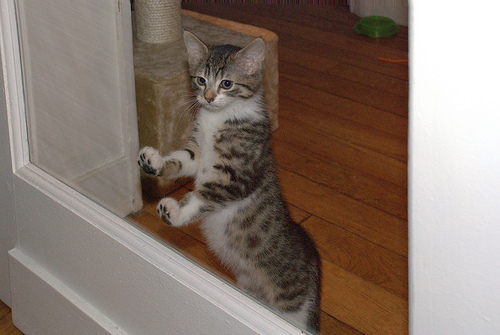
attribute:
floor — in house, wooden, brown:
[112, 1, 404, 334]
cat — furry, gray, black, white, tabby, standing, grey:
[135, 32, 319, 330]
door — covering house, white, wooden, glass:
[2, 4, 422, 334]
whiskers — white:
[176, 87, 205, 118]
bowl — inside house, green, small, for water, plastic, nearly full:
[350, 15, 396, 40]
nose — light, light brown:
[204, 92, 216, 103]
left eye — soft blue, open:
[220, 80, 234, 92]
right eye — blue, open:
[196, 75, 207, 88]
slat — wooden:
[277, 77, 407, 137]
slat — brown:
[280, 118, 409, 190]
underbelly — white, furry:
[192, 118, 263, 291]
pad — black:
[162, 205, 168, 213]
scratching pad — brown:
[134, 1, 189, 51]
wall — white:
[348, 1, 411, 31]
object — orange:
[367, 52, 409, 65]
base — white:
[13, 149, 299, 334]